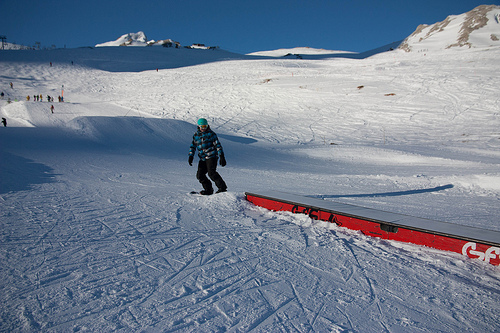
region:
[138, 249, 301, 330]
many lines in the snow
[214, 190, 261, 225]
mound of white snow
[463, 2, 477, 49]
mountain side without any snow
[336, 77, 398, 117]
brown spot in the snow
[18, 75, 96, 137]
skiers on the snow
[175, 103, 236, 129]
green cap on man's head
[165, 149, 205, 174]
black gloves on man's hand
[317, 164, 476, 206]
shadow of man in the snow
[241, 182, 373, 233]
red object in the snow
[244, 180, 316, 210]
black edge of the object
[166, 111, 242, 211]
A person in a snowsuit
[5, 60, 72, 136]
a crowd of people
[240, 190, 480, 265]
a red barrier for snowboarding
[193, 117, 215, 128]
a green hat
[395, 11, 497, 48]
a deserted mountaintop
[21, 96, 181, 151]
jumps for snowboarders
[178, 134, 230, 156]
a striped winter coat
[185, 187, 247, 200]
a snowboard being ridden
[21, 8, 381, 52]
a clear blue sky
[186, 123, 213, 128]
a pair of goggles on a snowboarder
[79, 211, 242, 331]
some tracks in the snow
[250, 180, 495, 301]
a long red jump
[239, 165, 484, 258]
a snow covered ramp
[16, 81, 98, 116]
a bunch of people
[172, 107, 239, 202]
a person snowboarding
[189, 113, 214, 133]
a bright blue helmet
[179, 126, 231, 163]
a blue striped snow jacket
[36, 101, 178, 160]
a large snow covered jump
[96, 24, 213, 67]
a snow covered mountain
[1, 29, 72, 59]
a ski lift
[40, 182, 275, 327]
snow is white and tracked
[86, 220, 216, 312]
snow is white and tracked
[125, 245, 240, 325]
snow is white and tracked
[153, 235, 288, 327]
snow is white and tracked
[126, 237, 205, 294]
snow is white and tracked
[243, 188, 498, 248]
red snowboard ramp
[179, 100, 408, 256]
snowboarder getting ready to do trick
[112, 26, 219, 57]
snow on the mountain tops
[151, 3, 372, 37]
clear blue sky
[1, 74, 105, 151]
snowboarders on the slope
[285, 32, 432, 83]
shadow of a mountain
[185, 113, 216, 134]
snowboarder is wearing a aqua hat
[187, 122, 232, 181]
snowboarder is wearing a blue and black checked jacket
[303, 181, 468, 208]
the shadow of the snowboarder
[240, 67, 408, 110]
grass patches in the snow